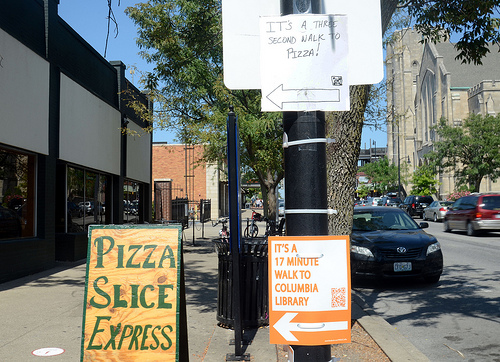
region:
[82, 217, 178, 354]
a small board of advertisement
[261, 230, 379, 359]
a mini board of add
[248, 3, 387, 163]
a white paper with text written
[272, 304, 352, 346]
a small left arrow mark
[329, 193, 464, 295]
a beautiful looking car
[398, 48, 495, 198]
a very big building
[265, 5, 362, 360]
a big black poll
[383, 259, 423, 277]
number plate of the car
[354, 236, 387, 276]
front light of the car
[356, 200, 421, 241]
front glass of the car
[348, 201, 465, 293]
Car parked on side of street.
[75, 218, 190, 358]
Wood sign trimmed in green advertising about pizza.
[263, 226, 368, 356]
Orange and white sign advertising about library.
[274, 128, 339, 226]
White zip ties around black post.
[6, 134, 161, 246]
Windows on side of business.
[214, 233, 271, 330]
Black metal trash bin on sidewalk.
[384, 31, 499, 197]
Large church on side of street.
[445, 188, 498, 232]
Red mini van moving in traffic down street.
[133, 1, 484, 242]
Green lush tree growing on sidewalk.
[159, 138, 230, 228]
Side of brown building next to sidewalk.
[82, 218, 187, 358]
an advertisement board is on a sidewalk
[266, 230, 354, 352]
a directional sign is on the pole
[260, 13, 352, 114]
a directional sign is hand written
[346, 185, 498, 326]
cars are parked curbside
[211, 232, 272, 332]
a black metal trash can is on the sidewalk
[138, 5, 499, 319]
trees line the city street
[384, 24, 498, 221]
a church is on the street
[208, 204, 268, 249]
bicycles are parked on the sidewalk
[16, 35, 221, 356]
store fronts on next to the sidewalk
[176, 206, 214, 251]
a chain fence is on the sidewalk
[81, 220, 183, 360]
the pizza slice express sign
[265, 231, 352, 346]
the orange and white sign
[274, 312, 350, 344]
the white arrow on the sign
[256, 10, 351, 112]
the hand written sign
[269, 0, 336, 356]
the black pole with signs on them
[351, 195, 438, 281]
the parked black car near the tree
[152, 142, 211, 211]
the brick building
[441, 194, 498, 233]
the red van on the road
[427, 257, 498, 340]
the trees shadow on the road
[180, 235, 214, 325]
the shadows on the sidewalk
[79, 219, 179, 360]
Pizza sign board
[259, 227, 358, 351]
A direction's sign to a library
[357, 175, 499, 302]
Cars on the street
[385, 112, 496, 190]
Trees on the street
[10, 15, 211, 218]
Buildings on the street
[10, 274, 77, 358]
Empty walkway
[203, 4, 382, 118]
A sign showing the time distace to a Pizza restaurant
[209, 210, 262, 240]
Bicycles parked on the street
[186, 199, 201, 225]
A person walking on the street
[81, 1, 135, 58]
Clear blue of the sky